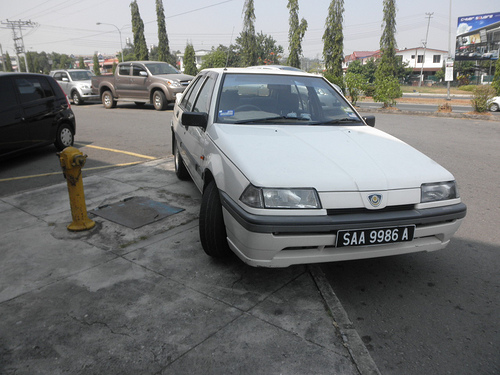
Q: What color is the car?
A: White.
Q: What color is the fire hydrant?
A: Yellow.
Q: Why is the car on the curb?
A: It is parked.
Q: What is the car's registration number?
A: SAA 9986 A.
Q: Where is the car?
A: On the curb.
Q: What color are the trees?
A: Green.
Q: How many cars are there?
A: Four.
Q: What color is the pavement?
A: Grey.